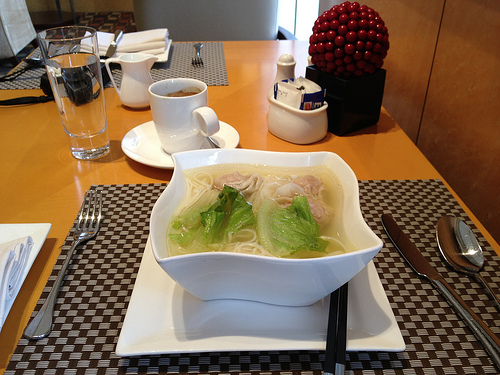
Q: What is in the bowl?
A: Soup.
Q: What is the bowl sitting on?
A: White plate.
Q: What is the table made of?
A: Wood.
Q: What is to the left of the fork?
A: White napkin.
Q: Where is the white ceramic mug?
A: In back of the bowl.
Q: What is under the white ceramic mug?
A: A saucer.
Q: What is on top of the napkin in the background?
A: Knife.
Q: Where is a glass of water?
A: Besides cup and saucer.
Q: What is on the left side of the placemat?
A: Stainless steel fork.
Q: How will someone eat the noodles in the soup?
A: With black chopsticks.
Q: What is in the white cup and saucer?
A: Tea or coffee.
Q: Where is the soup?
A: In the white dish.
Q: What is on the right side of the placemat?
A: Spoon and knife.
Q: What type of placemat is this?
A: Woven.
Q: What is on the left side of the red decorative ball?
A: Salt shaker and sachet holder.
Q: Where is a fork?
A: Left of soup.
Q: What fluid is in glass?
A: Water.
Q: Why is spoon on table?
A: To eat soup.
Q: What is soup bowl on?
A: Square white plate.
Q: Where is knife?
A: Right of soup.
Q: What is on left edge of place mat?
A: Fork.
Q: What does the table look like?
A: Wooden.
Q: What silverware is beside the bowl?
A: Knife,spoon and fork.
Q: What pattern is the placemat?
A: Plaid.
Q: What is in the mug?
A: Coffee.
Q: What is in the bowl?
A: Soup.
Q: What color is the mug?
A: White.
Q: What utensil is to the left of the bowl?
A: A fork.